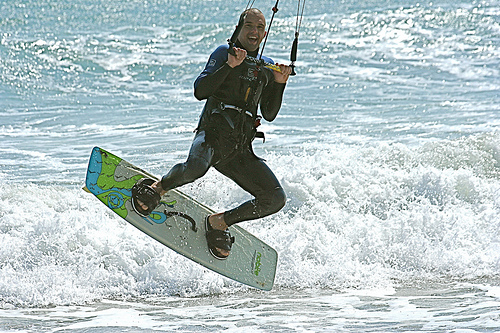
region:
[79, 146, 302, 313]
a white board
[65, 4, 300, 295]
a man who is riding a wakeboard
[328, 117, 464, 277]
waves in the water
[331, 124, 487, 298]
waves created by the boat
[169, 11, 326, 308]
the man who is wakeboarding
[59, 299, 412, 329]
water that is nice and blue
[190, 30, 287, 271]
the man's wetsuit so he does not get wet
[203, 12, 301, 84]
the handle for the man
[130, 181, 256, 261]
the man's feet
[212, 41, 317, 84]
the man's hands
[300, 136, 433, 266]
waves crashing in the ocean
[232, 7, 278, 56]
man with a big smile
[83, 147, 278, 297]
white,blue, and green mini surfboard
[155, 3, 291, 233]
man in a wet suit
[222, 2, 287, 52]
man with a shaved head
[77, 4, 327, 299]
man enjoying the ocean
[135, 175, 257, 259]
man that is bare foot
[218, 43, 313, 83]
man holding on to handle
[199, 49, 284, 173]
safety straps over wet suite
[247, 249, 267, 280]
brand name of board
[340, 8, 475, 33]
sun reflecting on water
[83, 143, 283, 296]
white, green and blue boogie board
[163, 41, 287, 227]
black wet suit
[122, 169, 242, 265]
black foot straps on boogie board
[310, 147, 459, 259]
white foam on wave tops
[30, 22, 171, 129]
light blue ocean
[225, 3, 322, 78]
man holding windsurfing handle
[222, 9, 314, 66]
ropes attached to parachute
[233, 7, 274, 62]
balding man with a smile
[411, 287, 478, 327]
bubbles forming in foam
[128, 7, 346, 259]
a man in a black wetsuit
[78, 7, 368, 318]
a man is parasailing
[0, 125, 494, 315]
a splashing white wave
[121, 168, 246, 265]
black foot clamps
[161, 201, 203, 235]
a black handle on the board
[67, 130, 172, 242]
green and blue decorations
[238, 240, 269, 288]
green letters on the board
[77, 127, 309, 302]
a white parasailing board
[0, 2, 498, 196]
blue water all around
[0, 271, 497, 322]
white foam on the ocean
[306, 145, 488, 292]
the tide is breaking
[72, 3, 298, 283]
man on a waterboard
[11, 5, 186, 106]
ocean is blue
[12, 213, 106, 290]
the wave is white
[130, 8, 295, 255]
the man is smiling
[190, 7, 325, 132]
the man is holding onto a bar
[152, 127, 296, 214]
the mans knees are bent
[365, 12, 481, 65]
the water is shiney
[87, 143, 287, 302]
the board is green, blue and white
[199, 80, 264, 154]
the man wears a harness